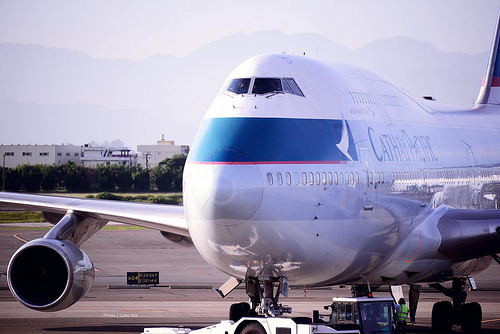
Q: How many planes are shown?
A: One.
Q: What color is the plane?
A: White.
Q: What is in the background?
A: Mountains.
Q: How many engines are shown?
A: One.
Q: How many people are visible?
A: One.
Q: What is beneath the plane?
A: Wheels.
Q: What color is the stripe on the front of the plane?
A: Blue.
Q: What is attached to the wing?
A: A jet turbine.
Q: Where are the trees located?
A: Past the runway.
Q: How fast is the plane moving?
A: It is parked.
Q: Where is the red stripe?
A: Below the blue stripe.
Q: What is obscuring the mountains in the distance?
A: Fog.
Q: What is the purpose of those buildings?
A: Office space.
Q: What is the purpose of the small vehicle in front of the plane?
A: Hauling luggage.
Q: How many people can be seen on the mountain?
A: 0.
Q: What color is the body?
A: White with blue and some red.